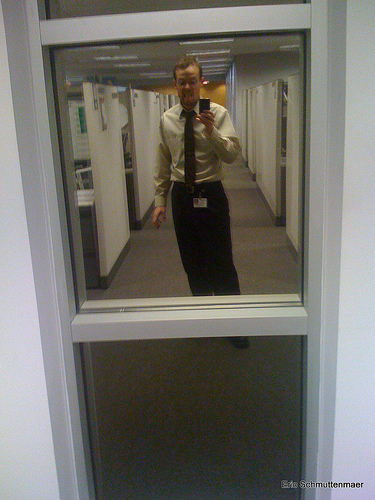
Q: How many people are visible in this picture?
A: One.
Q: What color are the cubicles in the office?
A: White.